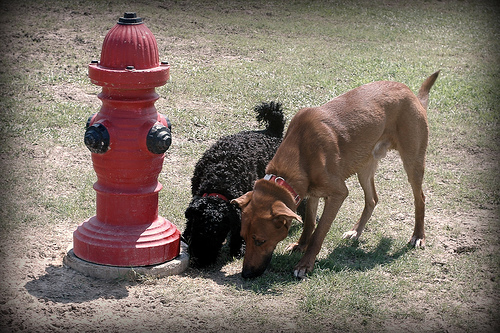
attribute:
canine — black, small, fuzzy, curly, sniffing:
[182, 97, 288, 267]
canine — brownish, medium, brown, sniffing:
[231, 67, 440, 278]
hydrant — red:
[72, 11, 180, 265]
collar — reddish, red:
[196, 190, 231, 202]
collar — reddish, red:
[263, 173, 304, 207]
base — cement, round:
[63, 237, 192, 281]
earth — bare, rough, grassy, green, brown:
[4, 3, 499, 331]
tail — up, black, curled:
[251, 101, 289, 136]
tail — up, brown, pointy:
[413, 69, 441, 111]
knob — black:
[146, 123, 171, 154]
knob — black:
[85, 123, 106, 154]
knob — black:
[84, 118, 88, 137]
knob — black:
[166, 117, 171, 133]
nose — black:
[192, 257, 207, 267]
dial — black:
[117, 11, 143, 26]